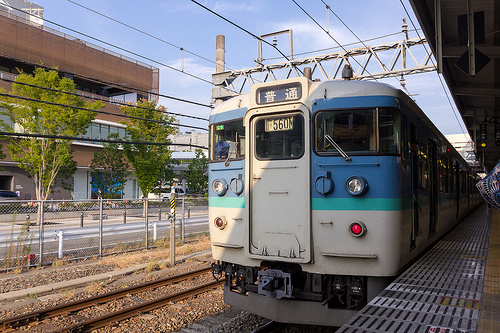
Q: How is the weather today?
A: It is cloudy.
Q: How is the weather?
A: It is cloudy.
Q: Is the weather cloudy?
A: Yes, it is cloudy.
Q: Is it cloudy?
A: Yes, it is cloudy.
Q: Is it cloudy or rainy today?
A: It is cloudy.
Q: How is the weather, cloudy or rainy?
A: It is cloudy.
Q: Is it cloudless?
A: No, it is cloudy.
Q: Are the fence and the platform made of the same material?
A: Yes, both the fence and the platform are made of metal.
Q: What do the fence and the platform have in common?
A: The material, both the fence and the platform are metallic.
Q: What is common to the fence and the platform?
A: The material, both the fence and the platform are metallic.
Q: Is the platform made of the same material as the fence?
A: Yes, both the platform and the fence are made of metal.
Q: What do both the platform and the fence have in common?
A: The material, both the platform and the fence are metallic.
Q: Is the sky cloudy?
A: Yes, the sky is cloudy.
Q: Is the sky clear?
A: No, the sky is cloudy.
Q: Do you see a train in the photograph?
A: Yes, there is a train.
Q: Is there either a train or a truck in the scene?
A: Yes, there is a train.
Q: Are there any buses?
A: No, there are no buses.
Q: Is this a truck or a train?
A: This is a train.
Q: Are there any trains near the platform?
A: Yes, there is a train near the platform.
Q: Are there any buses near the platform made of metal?
A: No, there is a train near the platform.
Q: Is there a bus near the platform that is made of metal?
A: No, there is a train near the platform.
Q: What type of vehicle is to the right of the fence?
A: The vehicle is a train.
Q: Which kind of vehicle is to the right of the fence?
A: The vehicle is a train.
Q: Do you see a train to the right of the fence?
A: Yes, there is a train to the right of the fence.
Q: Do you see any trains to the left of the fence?
A: No, the train is to the right of the fence.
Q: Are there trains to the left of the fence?
A: No, the train is to the right of the fence.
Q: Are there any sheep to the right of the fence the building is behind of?
A: No, there is a train to the right of the fence.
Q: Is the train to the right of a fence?
A: Yes, the train is to the right of a fence.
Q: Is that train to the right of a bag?
A: No, the train is to the right of a fence.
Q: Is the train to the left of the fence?
A: No, the train is to the right of the fence.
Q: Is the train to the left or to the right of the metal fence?
A: The train is to the right of the fence.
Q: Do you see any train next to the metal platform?
A: Yes, there is a train next to the platform.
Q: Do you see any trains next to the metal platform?
A: Yes, there is a train next to the platform.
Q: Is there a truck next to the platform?
A: No, there is a train next to the platform.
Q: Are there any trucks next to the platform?
A: No, there is a train next to the platform.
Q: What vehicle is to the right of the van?
A: The vehicle is a train.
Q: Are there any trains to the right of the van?
A: Yes, there is a train to the right of the van.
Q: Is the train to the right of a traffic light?
A: No, the train is to the right of a van.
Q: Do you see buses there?
A: No, there are no buses.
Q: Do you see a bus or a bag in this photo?
A: No, there are no buses or bags.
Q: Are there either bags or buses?
A: No, there are no buses or bags.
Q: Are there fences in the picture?
A: Yes, there is a fence.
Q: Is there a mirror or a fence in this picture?
A: Yes, there is a fence.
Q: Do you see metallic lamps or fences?
A: Yes, there is a metal fence.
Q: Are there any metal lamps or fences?
A: Yes, there is a metal fence.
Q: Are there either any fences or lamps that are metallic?
A: Yes, the fence is metallic.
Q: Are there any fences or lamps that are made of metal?
A: Yes, the fence is made of metal.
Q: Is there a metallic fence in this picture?
A: Yes, there is a metal fence.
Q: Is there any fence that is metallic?
A: Yes, there is a fence that is metallic.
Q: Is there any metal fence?
A: Yes, there is a fence that is made of metal.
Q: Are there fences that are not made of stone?
A: Yes, there is a fence that is made of metal.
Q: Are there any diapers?
A: No, there are no diapers.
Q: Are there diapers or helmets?
A: No, there are no diapers or helmets.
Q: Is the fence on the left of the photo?
A: Yes, the fence is on the left of the image.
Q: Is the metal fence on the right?
A: No, the fence is on the left of the image.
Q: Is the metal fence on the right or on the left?
A: The fence is on the left of the image.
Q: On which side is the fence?
A: The fence is on the left of the image.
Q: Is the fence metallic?
A: Yes, the fence is metallic.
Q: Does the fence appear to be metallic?
A: Yes, the fence is metallic.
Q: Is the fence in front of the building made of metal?
A: Yes, the fence is made of metal.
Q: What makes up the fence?
A: The fence is made of metal.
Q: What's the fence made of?
A: The fence is made of metal.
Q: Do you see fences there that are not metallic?
A: No, there is a fence but it is metallic.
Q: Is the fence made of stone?
A: No, the fence is made of metal.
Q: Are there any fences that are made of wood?
A: No, there is a fence but it is made of metal.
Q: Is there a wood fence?
A: No, there is a fence but it is made of metal.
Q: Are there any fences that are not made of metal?
A: No, there is a fence but it is made of metal.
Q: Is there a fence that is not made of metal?
A: No, there is a fence but it is made of metal.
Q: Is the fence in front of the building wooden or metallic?
A: The fence is metallic.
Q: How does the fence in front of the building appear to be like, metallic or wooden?
A: The fence is metallic.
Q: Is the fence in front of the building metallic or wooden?
A: The fence is metallic.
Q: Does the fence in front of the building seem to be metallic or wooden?
A: The fence is metallic.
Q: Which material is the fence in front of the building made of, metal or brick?
A: The fence is made of metal.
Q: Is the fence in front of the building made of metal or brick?
A: The fence is made of metal.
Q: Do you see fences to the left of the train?
A: Yes, there is a fence to the left of the train.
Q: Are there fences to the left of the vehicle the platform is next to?
A: Yes, there is a fence to the left of the train.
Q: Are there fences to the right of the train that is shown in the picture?
A: No, the fence is to the left of the train.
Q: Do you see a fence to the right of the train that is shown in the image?
A: No, the fence is to the left of the train.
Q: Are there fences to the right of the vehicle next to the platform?
A: No, the fence is to the left of the train.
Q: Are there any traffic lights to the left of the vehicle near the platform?
A: No, there is a fence to the left of the train.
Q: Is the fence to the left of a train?
A: Yes, the fence is to the left of a train.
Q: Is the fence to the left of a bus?
A: No, the fence is to the left of a train.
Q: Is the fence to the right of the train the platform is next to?
A: No, the fence is to the left of the train.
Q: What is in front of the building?
A: The fence is in front of the building.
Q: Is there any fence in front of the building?
A: Yes, there is a fence in front of the building.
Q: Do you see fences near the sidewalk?
A: Yes, there is a fence near the sidewalk.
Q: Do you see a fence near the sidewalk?
A: Yes, there is a fence near the sidewalk.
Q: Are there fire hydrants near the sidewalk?
A: No, there is a fence near the sidewalk.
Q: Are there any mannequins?
A: No, there are no mannequins.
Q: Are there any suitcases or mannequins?
A: No, there are no mannequins or suitcases.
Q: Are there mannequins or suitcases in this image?
A: No, there are no mannequins or suitcases.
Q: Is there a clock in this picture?
A: No, there are no clocks.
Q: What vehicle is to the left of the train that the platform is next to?
A: The vehicle is a van.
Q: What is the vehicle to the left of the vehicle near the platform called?
A: The vehicle is a van.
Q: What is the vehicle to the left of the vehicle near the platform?
A: The vehicle is a van.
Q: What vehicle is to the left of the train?
A: The vehicle is a van.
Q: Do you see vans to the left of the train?
A: Yes, there is a van to the left of the train.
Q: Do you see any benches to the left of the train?
A: No, there is a van to the left of the train.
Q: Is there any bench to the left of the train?
A: No, there is a van to the left of the train.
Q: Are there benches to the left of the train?
A: No, there is a van to the left of the train.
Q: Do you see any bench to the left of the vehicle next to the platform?
A: No, there is a van to the left of the train.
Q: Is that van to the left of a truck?
A: No, the van is to the left of the train.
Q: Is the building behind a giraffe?
A: No, the building is behind a fence.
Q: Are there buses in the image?
A: No, there are no buses.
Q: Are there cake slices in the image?
A: No, there are no cake slices.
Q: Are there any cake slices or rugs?
A: No, there are no cake slices or rugs.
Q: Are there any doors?
A: Yes, there is a door.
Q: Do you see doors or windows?
A: Yes, there is a door.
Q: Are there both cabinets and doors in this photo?
A: No, there is a door but no cabinets.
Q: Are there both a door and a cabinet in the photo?
A: No, there is a door but no cabinets.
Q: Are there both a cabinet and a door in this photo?
A: No, there is a door but no cabinets.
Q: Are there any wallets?
A: No, there are no wallets.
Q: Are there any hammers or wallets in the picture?
A: No, there are no wallets or hammers.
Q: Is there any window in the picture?
A: Yes, there is a window.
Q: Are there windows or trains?
A: Yes, there is a window.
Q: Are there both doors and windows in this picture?
A: Yes, there are both a window and a door.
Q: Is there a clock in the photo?
A: No, there are no clocks.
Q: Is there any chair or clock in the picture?
A: No, there are no clocks or chairs.